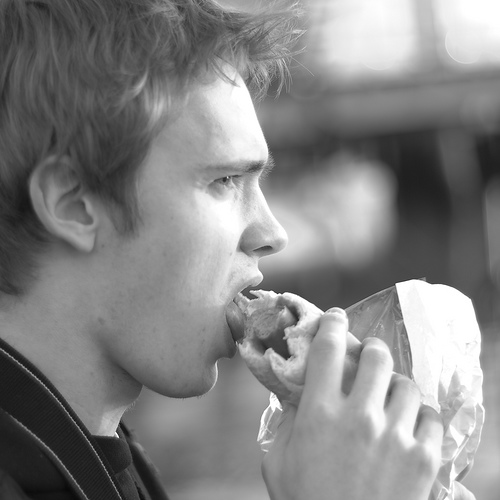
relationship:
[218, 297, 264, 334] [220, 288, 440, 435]
tongue touching bun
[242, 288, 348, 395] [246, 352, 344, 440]
hot dog in bun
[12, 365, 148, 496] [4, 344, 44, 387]
strap with trim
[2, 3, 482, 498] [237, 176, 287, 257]
man has nose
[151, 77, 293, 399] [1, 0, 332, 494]
face on man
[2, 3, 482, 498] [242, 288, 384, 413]
man eating hot dog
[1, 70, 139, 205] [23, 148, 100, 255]
hair covering ear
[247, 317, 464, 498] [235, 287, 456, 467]
hand holding hot dog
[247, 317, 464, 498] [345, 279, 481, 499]
hand holding package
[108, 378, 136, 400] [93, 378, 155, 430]
fuzz on neck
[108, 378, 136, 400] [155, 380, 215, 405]
fuzz on chin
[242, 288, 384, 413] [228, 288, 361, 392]
hot dog in bun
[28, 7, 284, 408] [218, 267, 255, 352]
man opening mouth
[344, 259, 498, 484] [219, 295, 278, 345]
wrapper wrapped around hot dog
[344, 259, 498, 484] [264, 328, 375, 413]
wrapper wrapped around bun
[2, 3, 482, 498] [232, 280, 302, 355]
man eating sausage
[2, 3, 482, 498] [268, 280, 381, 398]
man eating bun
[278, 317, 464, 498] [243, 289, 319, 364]
hand holding sausage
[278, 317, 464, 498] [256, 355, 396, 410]
hand holding bun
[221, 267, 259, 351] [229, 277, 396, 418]
mouth open to eat food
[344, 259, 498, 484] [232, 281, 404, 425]
wrapper around sandwich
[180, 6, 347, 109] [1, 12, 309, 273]
bangs of hair